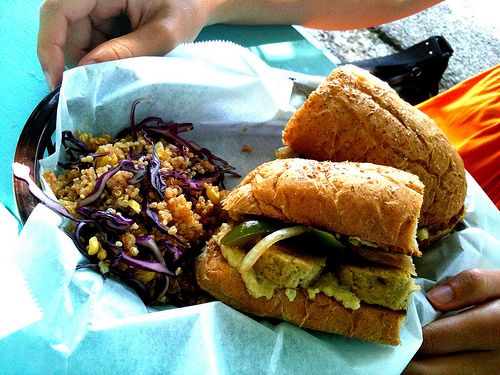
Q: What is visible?
A: A sandwich.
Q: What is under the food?
A: Paper.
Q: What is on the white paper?
A: Fingers.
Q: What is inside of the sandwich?
A: Meat.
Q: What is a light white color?
A: Paper.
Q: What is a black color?
A: Food basket.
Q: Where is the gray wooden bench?
A: Next to the table.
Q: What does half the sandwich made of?
A: Wheat bread, onions, and peppers.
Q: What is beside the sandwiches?
A: A side order of yellow corn with purple cabbage.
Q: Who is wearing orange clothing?
A: The person eating the food.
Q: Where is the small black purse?
A: Beside the person.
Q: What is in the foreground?
A: A large slice of sandwich.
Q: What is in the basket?
A: The basket is filled with food.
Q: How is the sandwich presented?
A: Cut in half.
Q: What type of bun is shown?
A: A hoagie.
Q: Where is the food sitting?
A: On blue paper.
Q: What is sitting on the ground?
A: A black bag.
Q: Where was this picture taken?
A: It was taken at a restaurant.